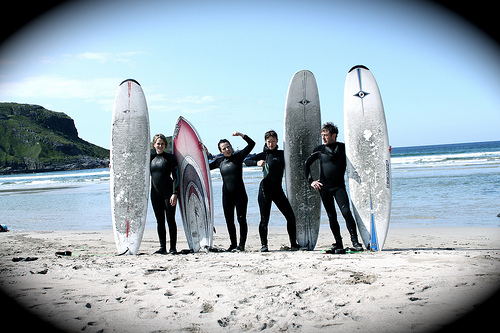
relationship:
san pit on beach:
[0, 232, 500, 333] [2, 185, 495, 331]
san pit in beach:
[0, 232, 500, 333] [5, 230, 497, 331]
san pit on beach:
[7, 221, 484, 331] [5, 230, 497, 331]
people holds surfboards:
[149, 121, 369, 252] [200, 43, 426, 292]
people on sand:
[149, 121, 369, 252] [0, 227, 498, 331]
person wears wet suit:
[214, 120, 301, 230] [143, 151, 186, 243]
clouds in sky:
[33, 35, 130, 115] [23, 16, 422, 102]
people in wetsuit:
[109, 133, 181, 254] [147, 151, 177, 254]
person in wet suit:
[244, 129, 303, 252] [244, 145, 296, 245]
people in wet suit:
[109, 133, 181, 254] [149, 152, 180, 249]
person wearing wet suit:
[244, 129, 303, 252] [240, 147, 300, 246]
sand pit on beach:
[0, 231, 500, 333] [5, 230, 497, 331]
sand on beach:
[203, 272, 323, 317] [283, 232, 400, 297]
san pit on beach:
[0, 232, 500, 333] [5, 230, 497, 331]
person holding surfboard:
[304, 122, 361, 253] [345, 63, 392, 250]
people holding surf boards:
[149, 121, 369, 252] [103, 65, 391, 252]